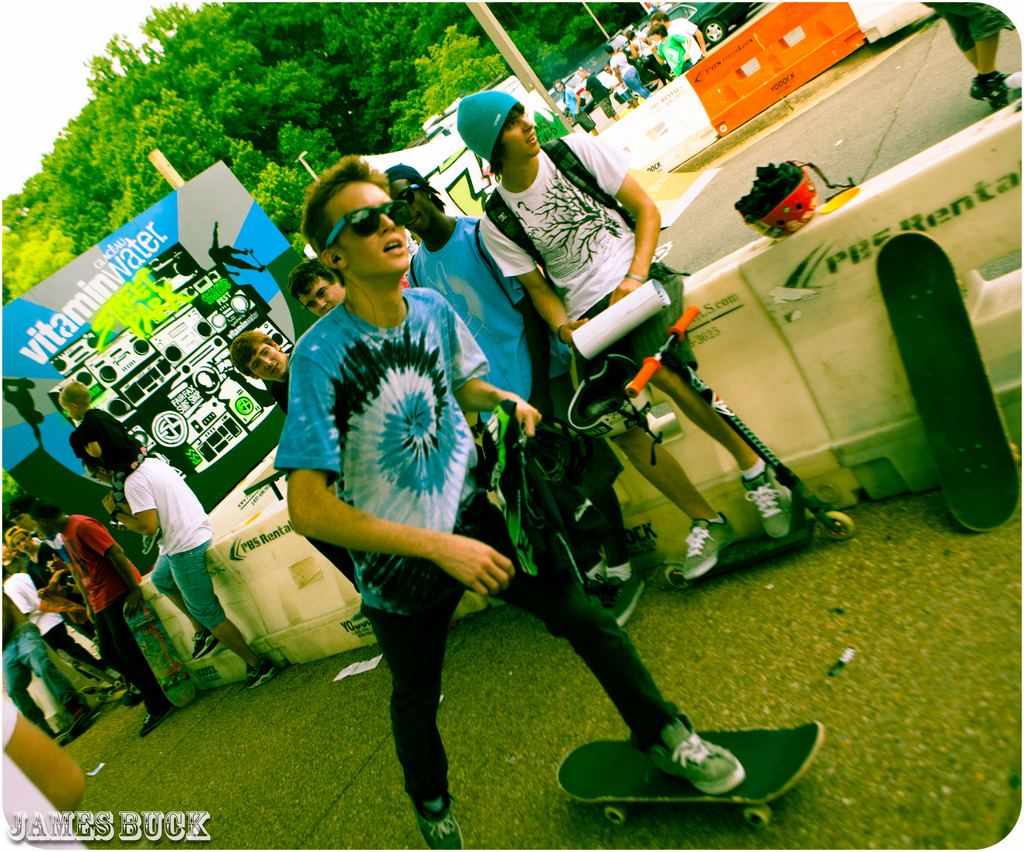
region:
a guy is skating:
[280, 159, 824, 849]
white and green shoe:
[652, 717, 741, 795]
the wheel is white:
[738, 799, 774, 826]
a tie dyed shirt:
[283, 290, 487, 614]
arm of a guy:
[286, 469, 512, 591]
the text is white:
[19, 220, 165, 363]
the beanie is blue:
[452, 92, 514, 150]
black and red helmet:
[734, 159, 815, 242]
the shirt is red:
[62, 514, 138, 610]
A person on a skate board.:
[276, 159, 815, 834]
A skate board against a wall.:
[867, 216, 1011, 552]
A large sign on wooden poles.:
[3, 164, 324, 576]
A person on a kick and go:
[462, 88, 873, 595]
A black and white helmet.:
[560, 341, 656, 440]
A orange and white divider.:
[598, 0, 932, 182]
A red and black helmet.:
[733, 157, 842, 243]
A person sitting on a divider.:
[82, 426, 275, 696]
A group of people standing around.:
[545, 0, 722, 138]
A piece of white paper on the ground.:
[336, 647, 382, 687]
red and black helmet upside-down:
[725, 152, 871, 244]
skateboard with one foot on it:
[554, 715, 829, 829]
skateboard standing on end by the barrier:
[863, 223, 1016, 544]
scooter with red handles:
[582, 299, 861, 585]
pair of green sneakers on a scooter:
[655, 456, 805, 586]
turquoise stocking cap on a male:
[446, 80, 524, 169]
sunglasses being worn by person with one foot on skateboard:
[316, 195, 415, 246]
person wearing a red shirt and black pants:
[20, 486, 179, 743]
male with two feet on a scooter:
[445, 78, 870, 585]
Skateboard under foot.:
[546, 720, 831, 826]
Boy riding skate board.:
[268, 153, 753, 850]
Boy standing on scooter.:
[445, 87, 803, 578]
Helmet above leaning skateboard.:
[719, 159, 822, 240]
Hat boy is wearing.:
[444, 86, 521, 166]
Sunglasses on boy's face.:
[317, 194, 409, 248]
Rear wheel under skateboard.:
[590, 792, 626, 819]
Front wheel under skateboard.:
[734, 795, 773, 828]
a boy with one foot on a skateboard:
[247, 154, 876, 834]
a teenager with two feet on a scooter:
[448, 91, 869, 598]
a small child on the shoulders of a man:
[38, 382, 168, 522]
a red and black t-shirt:
[46, 515, 138, 637]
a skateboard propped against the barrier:
[856, 231, 1022, 532]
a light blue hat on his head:
[446, 91, 536, 159]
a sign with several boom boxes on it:
[0, 162, 354, 556]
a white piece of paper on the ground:
[319, 658, 400, 684]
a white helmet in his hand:
[561, 329, 670, 467]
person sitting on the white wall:
[378, 172, 645, 594]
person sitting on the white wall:
[95, 397, 277, 689]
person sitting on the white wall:
[216, 306, 381, 643]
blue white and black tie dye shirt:
[274, 295, 535, 594]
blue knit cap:
[458, 76, 510, 156]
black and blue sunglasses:
[322, 203, 409, 255]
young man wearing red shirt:
[32, 478, 175, 722]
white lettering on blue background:
[9, 235, 194, 357]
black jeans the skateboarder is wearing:
[348, 534, 663, 790]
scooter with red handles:
[591, 304, 860, 579]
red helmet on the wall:
[736, 155, 817, 232]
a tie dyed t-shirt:
[272, 288, 489, 611]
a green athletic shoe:
[642, 714, 738, 795]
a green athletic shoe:
[416, 808, 464, 850]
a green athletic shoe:
[677, 509, 736, 577]